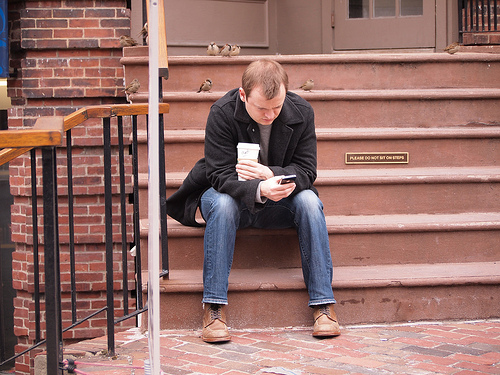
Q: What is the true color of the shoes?
A: Brown.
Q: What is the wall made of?
A: Bricks.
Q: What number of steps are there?
A: 6.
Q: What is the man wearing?
A: Jeans.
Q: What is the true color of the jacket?
A: Black.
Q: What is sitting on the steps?
A: A man.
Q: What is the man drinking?
A: A hot beverage.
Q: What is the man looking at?
A: His phone.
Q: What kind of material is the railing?
A: Wood.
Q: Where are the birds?
A: On the steps.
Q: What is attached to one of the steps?
A: A plaque.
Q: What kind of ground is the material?
A: Brick.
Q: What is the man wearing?
A: A coat.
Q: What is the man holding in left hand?
A: A cup.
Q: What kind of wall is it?
A: Brick.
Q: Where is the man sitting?
A: Exterior building front steps.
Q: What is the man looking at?
A: Cell phone.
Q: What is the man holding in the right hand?
A: Coffee cup.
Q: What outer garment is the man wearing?
A: Black coat.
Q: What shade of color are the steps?
A: Red clay.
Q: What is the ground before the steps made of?
A: Bricks.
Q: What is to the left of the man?
A: Metal hand rail.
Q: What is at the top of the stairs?
A: Two doors.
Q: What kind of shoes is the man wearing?
A: Boots.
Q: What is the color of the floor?
A: Red.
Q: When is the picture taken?
A: Daytime.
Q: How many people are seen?
A: 1.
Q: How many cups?
A: One.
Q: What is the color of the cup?
A: White.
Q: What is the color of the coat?
A: Black.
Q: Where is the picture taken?
A: On steps.